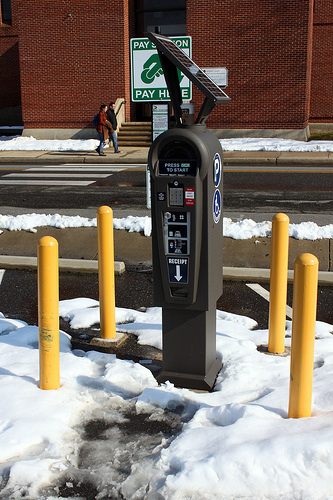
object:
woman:
[95, 100, 111, 156]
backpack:
[89, 114, 99, 128]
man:
[106, 101, 121, 154]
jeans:
[108, 132, 122, 155]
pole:
[35, 234, 64, 394]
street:
[2, 165, 329, 208]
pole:
[95, 203, 118, 343]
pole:
[266, 212, 289, 358]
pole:
[284, 251, 322, 423]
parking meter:
[145, 26, 231, 393]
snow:
[5, 208, 149, 239]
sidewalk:
[2, 191, 333, 280]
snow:
[221, 214, 332, 240]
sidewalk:
[0, 132, 333, 163]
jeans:
[97, 136, 107, 152]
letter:
[134, 88, 143, 98]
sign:
[126, 33, 192, 101]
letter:
[141, 88, 148, 102]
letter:
[148, 87, 157, 102]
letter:
[158, 88, 167, 99]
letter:
[134, 41, 140, 50]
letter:
[139, 40, 146, 50]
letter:
[180, 86, 190, 99]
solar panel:
[149, 29, 233, 103]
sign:
[210, 154, 224, 187]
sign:
[210, 189, 224, 225]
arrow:
[174, 263, 184, 283]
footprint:
[3, 442, 47, 492]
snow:
[2, 323, 133, 500]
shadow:
[75, 372, 259, 436]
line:
[2, 178, 97, 189]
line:
[3, 168, 115, 181]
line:
[24, 162, 126, 178]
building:
[13, 2, 332, 144]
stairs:
[115, 117, 155, 145]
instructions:
[156, 159, 198, 285]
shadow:
[47, 152, 99, 157]